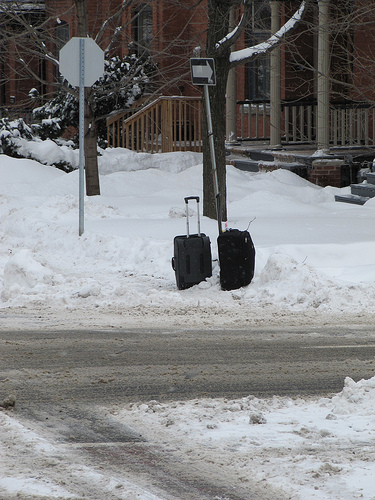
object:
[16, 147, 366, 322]
snow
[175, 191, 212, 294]
luggage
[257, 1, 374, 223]
tree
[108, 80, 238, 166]
steps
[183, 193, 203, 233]
handle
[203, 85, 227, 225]
pole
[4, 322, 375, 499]
track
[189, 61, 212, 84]
arrow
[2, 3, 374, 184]
building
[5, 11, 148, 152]
bushes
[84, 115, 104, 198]
trunk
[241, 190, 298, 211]
mountain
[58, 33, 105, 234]
sign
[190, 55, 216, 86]
sign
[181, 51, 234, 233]
sign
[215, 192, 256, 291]
suitcase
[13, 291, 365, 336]
sludge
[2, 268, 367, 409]
road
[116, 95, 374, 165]
porch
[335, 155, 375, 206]
stairs